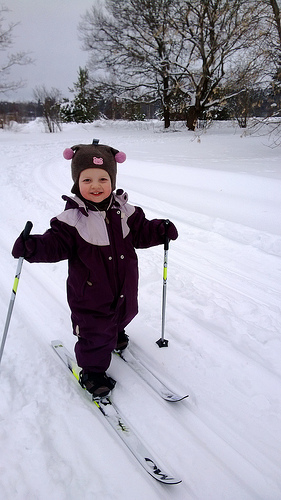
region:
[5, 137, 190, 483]
young girl with ski equipment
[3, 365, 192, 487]
one pair of white skis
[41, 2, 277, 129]
trees covered in snow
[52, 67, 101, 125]
pine tree after snowing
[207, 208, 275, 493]
roadway after it snowed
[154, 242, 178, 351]
white ski stick with yellow stripe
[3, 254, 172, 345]
two white ski sticks with yellow stripes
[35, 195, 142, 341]
buttoned up purple jacket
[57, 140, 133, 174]
brown and pink girl's hat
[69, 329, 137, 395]
feet clasps on the skis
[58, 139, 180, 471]
a child snow skiing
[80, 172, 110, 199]
a face of a chile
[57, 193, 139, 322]
a pink and brown winter coat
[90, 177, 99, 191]
a nose of a child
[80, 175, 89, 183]
an eye of a child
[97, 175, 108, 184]
an eye of a child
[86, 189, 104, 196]
a mouth of a child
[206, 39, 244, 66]
the branches of a tree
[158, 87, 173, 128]
the trunk of a tree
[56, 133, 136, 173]
a brown and pink stocking cap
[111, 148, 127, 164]
Pink ball on side of hat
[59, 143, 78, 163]
Pink ball on side of hat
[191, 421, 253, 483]
Ski tracks in white snow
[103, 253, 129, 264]
White buttons on pink ski jacket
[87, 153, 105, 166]
Pink frog image on hat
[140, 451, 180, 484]
Brand wording on tip of ski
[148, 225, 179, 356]
White and grey ski pole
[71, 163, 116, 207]
Smiling face of young girl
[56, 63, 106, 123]
Snow covered evergreen tree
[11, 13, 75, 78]
A snowy grey sky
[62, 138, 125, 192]
a knit ski cap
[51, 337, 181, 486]
a white pair of skis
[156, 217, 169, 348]
the young skier has ski poles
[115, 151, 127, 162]
pink pom poms on the cap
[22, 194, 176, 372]
a purple ski suit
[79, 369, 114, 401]
ski boot straps or binder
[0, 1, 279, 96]
grey sky's in the distance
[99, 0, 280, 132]
tall deciduous trees behind the skier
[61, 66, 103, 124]
an evergreen behind the skier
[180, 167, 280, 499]
a well groomed ski trail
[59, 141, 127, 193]
A beanie on her head.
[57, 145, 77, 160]
A pink fuzz ball.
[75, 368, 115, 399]
A boot on the skii.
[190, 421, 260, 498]
Skii marks on the ground.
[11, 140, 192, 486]
A child on skiis.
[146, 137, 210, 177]
Snow on the ground.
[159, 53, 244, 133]
Snow on the tree.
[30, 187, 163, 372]
The jumpsuit is purple.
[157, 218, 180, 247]
She grabs the handle.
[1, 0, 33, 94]
Brnaches with no leaves.